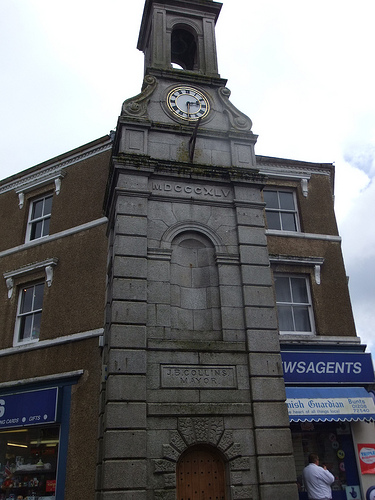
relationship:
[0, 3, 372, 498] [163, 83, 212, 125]
building has clock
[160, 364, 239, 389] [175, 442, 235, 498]
plaque above door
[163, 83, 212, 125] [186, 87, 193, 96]
clock uses roman numerals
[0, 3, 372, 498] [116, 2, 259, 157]
building has clock tower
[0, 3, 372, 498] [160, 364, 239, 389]
building has sign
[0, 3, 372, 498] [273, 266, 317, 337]
building has window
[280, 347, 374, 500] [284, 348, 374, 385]
store has blue sign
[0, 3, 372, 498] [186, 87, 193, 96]
building has roman numerals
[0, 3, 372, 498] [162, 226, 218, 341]
building has alcove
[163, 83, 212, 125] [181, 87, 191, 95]
clock has black numerals